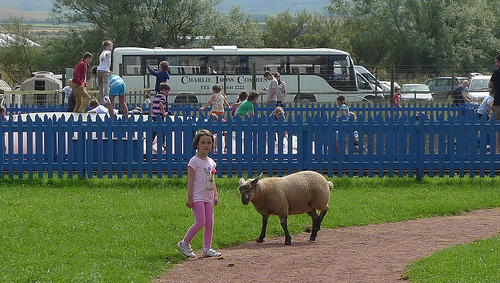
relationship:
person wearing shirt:
[72, 52, 101, 112] [70, 62, 90, 87]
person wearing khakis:
[72, 52, 101, 112] [74, 80, 91, 112]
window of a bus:
[334, 60, 351, 82] [112, 45, 359, 119]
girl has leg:
[154, 130, 254, 267] [198, 201, 227, 258]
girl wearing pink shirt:
[157, 124, 242, 264] [177, 151, 229, 210]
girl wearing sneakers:
[157, 124, 242, 264] [181, 237, 218, 259]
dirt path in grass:
[150, 206, 497, 280] [14, 181, 117, 281]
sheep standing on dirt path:
[227, 164, 344, 250] [150, 206, 497, 280]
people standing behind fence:
[70, 40, 373, 158] [2, 91, 499, 193]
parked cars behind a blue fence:
[343, 52, 499, 104] [0, 95, 499, 191]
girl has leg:
[178, 127, 218, 255] [176, 202, 203, 258]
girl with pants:
[157, 124, 242, 264] [178, 198, 220, 254]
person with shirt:
[233, 88, 263, 124] [236, 96, 259, 126]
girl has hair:
[157, 124, 242, 264] [189, 127, 216, 157]